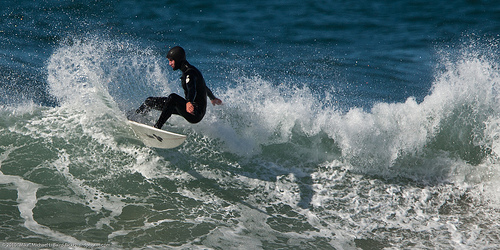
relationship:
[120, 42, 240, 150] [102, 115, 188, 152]
person riding surfboard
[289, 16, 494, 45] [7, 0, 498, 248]
ripple in water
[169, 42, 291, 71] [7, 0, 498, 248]
ripple in water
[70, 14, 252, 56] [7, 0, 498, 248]
ripple in water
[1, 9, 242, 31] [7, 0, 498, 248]
ripple in water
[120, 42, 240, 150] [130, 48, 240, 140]
person in wet suit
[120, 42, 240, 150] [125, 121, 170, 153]
person on surfboard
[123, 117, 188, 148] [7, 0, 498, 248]
white surfboard on water